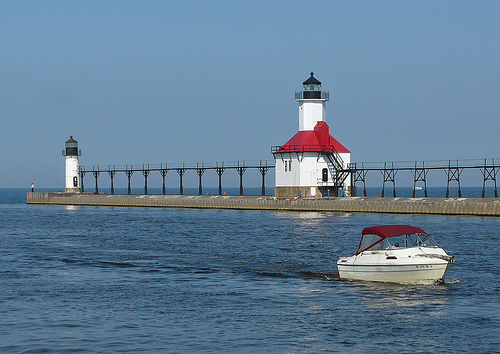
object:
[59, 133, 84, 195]
lighthouse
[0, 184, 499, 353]
water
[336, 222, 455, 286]
boat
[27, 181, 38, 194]
man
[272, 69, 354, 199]
building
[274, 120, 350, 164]
roof